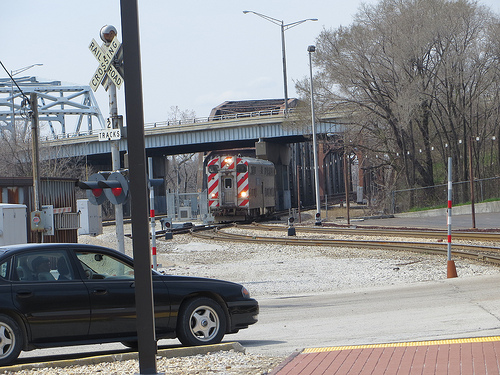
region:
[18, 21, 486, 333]
a train in the city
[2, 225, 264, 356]
a car waiting for a train to cross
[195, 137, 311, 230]
a train moving on the tracks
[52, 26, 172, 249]
railroad crossing sign for traffic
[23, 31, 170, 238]
railroad crossing equipment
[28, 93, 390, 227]
a bridge over the train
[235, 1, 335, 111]
a light pole in the area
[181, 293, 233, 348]
rims on a car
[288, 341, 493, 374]
a red brick sidewalk with a yellow stripe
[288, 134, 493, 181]
string lights in the area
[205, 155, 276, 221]
A train on a track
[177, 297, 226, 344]
A right front tire on a car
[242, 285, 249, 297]
A headlight on a car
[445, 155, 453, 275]
A red and white striped indicator on a railroad track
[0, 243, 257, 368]
A black sedan driving by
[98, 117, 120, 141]
A sign that says 2 Tracks on a train track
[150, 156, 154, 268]
A striped pole at a train track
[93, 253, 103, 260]
The mirror inside a car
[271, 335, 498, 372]
A red section of pavement by a train track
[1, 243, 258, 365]
A black car driving on a road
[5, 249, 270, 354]
black car is stopped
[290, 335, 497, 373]
red brick on ground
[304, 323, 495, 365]
yellow line on red brick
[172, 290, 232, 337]
car has black wheels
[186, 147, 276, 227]
red and grey train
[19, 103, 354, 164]
green bridge over train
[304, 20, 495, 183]
bare trees beside train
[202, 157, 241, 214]
red and white stripes on train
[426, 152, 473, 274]
red white and grey pole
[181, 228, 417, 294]
grey gravel next to track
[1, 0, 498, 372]
A railroad crossing scene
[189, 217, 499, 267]
These are train tracks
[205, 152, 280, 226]
A train is on the tracks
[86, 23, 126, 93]
A railroad crossing sign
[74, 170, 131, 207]
Railroad crossing signal lights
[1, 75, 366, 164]
A bridge is over the train tracks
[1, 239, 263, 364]
A car is stopped at the crossing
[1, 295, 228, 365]
The car's wheels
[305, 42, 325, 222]
A light post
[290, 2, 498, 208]
Trees are in the background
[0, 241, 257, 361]
a car on the street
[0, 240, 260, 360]
The car is a black car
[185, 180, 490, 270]
Train tracks on the ground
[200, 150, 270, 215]
A train on the tracks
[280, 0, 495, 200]
Trees on the side of the tracks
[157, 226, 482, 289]
rocks on the ground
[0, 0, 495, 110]
a calm pretty sky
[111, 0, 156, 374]
a pole beside the car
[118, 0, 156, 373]
The pole is long and black